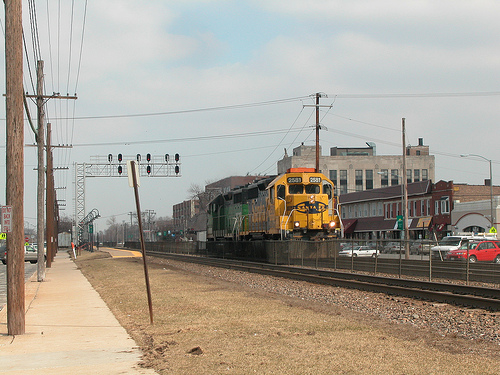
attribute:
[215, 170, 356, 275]
train car — yellow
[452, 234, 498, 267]
red car — Red 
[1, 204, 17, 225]
street sign — Red , white 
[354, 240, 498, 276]
fence — Chain link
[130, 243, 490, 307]
train tracks — Steel 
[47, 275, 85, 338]
cement sidewalk — White 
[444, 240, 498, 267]
red car — red , parked 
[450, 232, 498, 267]
red vehicle — red 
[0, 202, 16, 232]
sign — red , white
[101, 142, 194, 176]
signals — train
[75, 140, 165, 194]
structure — support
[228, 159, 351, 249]
locomotive — yellow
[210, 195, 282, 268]
cars — black, green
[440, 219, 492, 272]
car — small, red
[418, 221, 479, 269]
van — white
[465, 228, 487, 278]
car — red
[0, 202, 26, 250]
sign — white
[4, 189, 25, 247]
letters — red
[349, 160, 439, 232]
building — brick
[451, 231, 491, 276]
car — small, red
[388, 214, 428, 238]
sign — green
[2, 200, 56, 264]
sign — white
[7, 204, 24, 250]
letters — red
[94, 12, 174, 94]
clouds — white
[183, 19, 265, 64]
sky — blue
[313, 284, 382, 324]
rocks — small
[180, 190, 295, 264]
train car — green